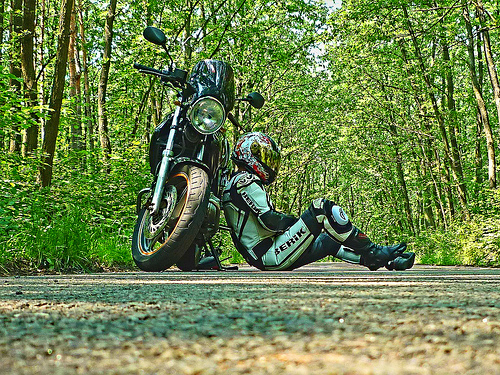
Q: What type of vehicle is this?
A: Motorcycle.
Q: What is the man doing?
A: Sitting.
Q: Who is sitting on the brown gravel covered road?
A: A man.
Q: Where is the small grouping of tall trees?
A: To the left.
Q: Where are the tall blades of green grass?
A: Beside the motorcycle.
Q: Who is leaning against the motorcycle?
A: A man.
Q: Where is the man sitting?
A: On the ground.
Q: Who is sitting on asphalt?
A: A man.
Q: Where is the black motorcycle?
A: Parked in the road.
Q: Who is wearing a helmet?
A: The bike racer.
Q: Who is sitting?
A: The bike racer.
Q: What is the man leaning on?
A: Bike.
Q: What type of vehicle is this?
A: Motorcycle.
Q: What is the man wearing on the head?
A: Helmet.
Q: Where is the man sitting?
A: Road.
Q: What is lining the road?
A: Trees.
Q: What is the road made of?
A: Asphalt.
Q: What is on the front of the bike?
A: Light.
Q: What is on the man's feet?
A: Boots.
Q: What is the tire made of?
A: Rubber.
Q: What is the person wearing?
A: Bike gear.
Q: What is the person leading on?
A: Motorcycle.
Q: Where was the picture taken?
A: A road.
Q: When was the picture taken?
A: Daytime.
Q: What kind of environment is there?
A: Forest.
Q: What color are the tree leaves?
A: Green.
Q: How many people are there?
A: One.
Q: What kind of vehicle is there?
A: A motorcycle.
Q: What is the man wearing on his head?
A: A helmet.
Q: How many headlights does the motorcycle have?
A: One.